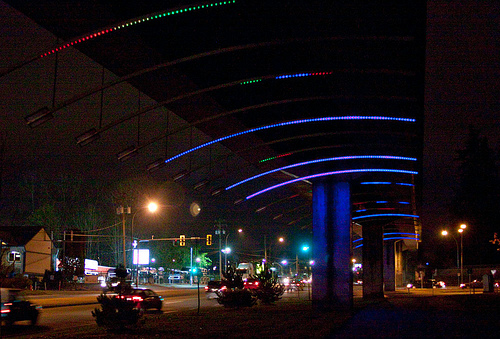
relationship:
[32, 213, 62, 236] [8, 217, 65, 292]
edge of building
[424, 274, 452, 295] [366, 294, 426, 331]
part of path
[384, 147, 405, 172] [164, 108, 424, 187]
part of light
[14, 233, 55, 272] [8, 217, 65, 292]
part of house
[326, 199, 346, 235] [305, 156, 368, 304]
part of pillar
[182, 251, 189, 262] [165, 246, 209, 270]
part of bush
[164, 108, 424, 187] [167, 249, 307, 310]
light of car